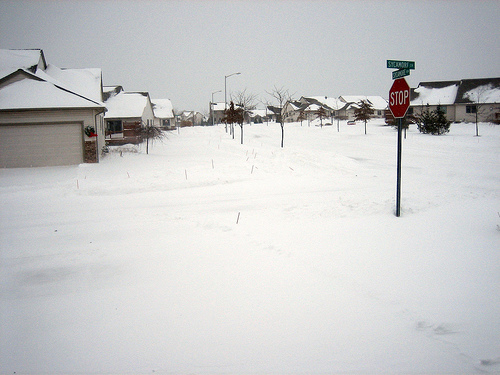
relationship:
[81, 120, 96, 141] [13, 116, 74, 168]
wreath on house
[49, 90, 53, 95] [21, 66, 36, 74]
snow on roof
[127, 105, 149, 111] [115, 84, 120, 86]
snow on roof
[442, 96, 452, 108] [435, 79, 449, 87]
snow on roof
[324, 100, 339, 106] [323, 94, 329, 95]
snow on roof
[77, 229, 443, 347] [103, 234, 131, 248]
yard covered in snow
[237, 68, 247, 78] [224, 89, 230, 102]
light on pole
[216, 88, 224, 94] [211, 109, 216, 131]
light on pole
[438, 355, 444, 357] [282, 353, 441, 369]
snow on street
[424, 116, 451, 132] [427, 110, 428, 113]
bush with leaves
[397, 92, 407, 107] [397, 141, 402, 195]
stop sign on pole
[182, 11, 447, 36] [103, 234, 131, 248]
sky over snow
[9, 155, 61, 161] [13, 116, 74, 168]
garage door on house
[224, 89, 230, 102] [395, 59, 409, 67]
pole on street sign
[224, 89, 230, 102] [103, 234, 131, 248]
pole in snow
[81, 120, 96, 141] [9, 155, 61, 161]
wreath on garage door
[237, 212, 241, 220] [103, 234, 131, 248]
stick in snow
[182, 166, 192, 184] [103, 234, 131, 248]
stick in snow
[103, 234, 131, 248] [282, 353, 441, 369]
snow on street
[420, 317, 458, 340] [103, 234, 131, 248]
footprint in snow